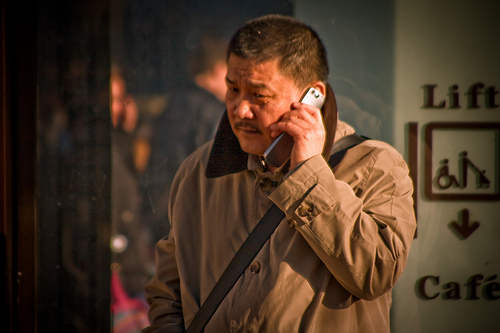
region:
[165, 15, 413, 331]
a man on the phone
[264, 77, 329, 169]
the phone in their hand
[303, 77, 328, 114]
the phone to his ear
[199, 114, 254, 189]
The collar of his coat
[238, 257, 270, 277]
button on the coat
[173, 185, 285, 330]
a black strap for the bag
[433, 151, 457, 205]
a sign of a wheelchair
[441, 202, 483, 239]
an arow pointing down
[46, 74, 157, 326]
the window of the building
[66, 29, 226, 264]
people behind the window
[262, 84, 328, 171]
a silver cell phone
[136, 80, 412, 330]
a long tan jacket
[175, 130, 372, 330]
a leather cross body strap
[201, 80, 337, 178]
a large brown collar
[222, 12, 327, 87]
short cut black hair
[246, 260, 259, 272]
a button on a jacket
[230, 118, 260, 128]
mustache on man's face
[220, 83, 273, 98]
eyes of man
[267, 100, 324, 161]
a man's hand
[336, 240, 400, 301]
elbow of man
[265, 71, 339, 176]
silver flip phone in hand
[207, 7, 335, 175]
asian man looking down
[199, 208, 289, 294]
eather strap to messenger bag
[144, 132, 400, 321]
light brown jacket with buttons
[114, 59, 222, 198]
blurry background of people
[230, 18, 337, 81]
black spiky hair on man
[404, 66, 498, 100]
the word lift on a wall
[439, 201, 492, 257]
a brown arrow facing down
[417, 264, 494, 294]
the word cafe on the wall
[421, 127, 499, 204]
a handicap sign on the wall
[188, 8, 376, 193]
man is talking on phone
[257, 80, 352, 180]
the phone is gray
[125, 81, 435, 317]
man's jacket is brown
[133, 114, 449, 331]
strap around man's shoulder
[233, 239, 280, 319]
buttons on jacket are brown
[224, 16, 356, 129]
man's hair is black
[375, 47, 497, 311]
letters on wall are brown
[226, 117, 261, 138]
man has moustache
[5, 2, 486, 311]
glass window behind man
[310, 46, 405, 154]
reflection of man in window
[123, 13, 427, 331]
man talking on phone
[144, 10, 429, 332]
man with short dark brown hair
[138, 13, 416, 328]
man with dark moustache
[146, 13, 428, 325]
man talking on long older model cell phone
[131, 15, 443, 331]
man wearing a tan coat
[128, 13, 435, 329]
man wearing a crossbody type shoulder bag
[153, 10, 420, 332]
man wearing collared jacket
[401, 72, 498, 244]
sign for wheelchair accessible area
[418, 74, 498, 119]
sign that says "lift"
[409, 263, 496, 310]
sign indicating an area with food